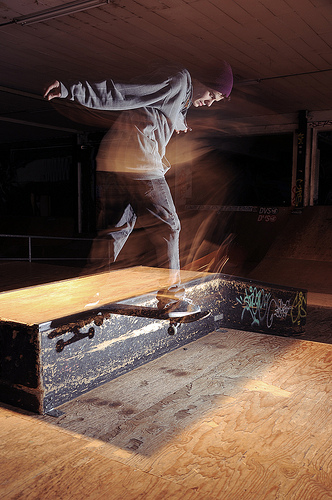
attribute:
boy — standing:
[37, 52, 246, 320]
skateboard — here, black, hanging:
[64, 303, 219, 339]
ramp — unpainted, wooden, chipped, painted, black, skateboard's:
[2, 261, 222, 326]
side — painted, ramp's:
[41, 276, 220, 410]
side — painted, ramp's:
[225, 275, 305, 339]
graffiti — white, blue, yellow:
[229, 278, 316, 329]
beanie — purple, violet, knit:
[190, 53, 238, 100]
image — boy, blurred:
[3, 0, 331, 482]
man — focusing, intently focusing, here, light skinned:
[24, 49, 238, 317]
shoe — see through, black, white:
[157, 295, 204, 319]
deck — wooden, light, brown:
[6, 255, 220, 330]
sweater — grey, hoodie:
[60, 62, 196, 172]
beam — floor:
[0, 262, 223, 326]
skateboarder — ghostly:
[41, 58, 241, 323]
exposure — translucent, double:
[11, 5, 331, 496]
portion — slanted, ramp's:
[192, 275, 324, 333]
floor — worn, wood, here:
[4, 330, 331, 491]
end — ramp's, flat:
[32, 299, 160, 407]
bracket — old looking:
[45, 406, 66, 423]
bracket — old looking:
[217, 324, 235, 336]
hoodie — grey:
[60, 64, 199, 187]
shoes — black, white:
[88, 296, 204, 323]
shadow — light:
[193, 323, 324, 405]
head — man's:
[187, 55, 240, 115]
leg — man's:
[131, 178, 185, 295]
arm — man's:
[58, 72, 188, 126]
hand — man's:
[38, 77, 64, 106]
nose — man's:
[204, 97, 217, 106]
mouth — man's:
[197, 99, 207, 109]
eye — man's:
[204, 86, 220, 97]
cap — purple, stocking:
[187, 60, 239, 95]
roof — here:
[4, 0, 330, 128]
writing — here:
[229, 284, 307, 328]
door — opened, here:
[195, 124, 294, 200]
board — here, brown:
[106, 302, 220, 334]